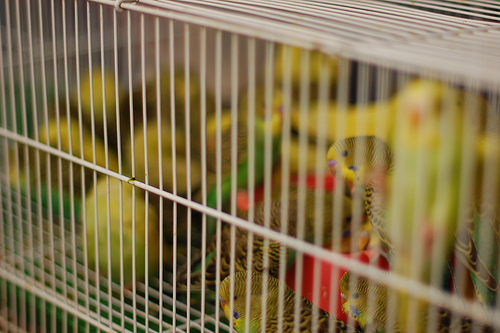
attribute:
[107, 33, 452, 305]
bird cage — metal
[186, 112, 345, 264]
bird — green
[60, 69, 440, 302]
birds — mixed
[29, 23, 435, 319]
birds — pets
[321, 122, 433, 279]
bird — captured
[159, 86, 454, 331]
birds — flock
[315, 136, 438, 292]
bird — captive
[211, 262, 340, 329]
bird — captive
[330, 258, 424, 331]
bird — captive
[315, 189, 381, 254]
bird — eating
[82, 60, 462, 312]
birds — red, green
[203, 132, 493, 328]
chics — separated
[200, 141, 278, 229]
parakeets — yellow, green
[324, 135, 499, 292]
bird — yellow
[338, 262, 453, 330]
bird — yellow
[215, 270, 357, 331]
bird — yellow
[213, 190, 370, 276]
bird — yellow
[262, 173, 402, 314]
dish — feeding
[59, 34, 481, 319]
birds — yellow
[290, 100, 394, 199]
bird — yellow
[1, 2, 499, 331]
cage — white